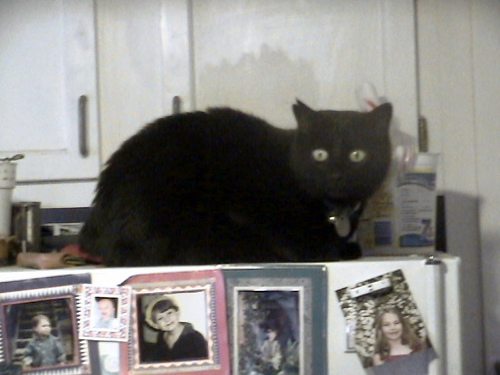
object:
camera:
[56, 83, 414, 284]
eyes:
[342, 145, 367, 164]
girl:
[367, 299, 440, 374]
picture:
[334, 270, 433, 372]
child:
[144, 293, 207, 361]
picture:
[114, 270, 230, 375]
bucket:
[1, 152, 23, 262]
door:
[10, 5, 101, 185]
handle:
[74, 88, 92, 155]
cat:
[76, 100, 393, 267]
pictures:
[3, 282, 81, 368]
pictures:
[78, 284, 133, 343]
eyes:
[310, 146, 337, 169]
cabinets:
[2, 8, 427, 209]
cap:
[144, 295, 180, 331]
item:
[14, 199, 41, 255]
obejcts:
[1, 143, 51, 256]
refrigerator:
[4, 255, 483, 372]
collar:
[327, 207, 353, 236]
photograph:
[210, 262, 325, 375]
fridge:
[3, 257, 481, 370]